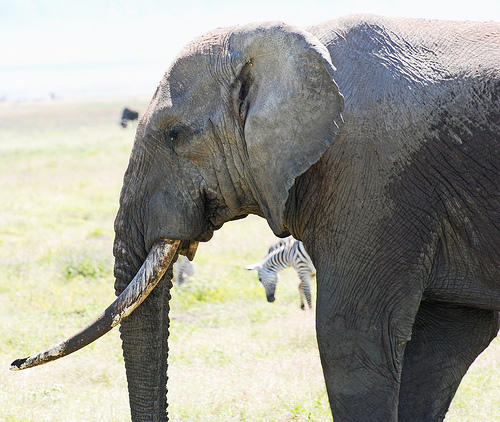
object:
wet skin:
[360, 75, 500, 291]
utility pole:
[243, 232, 316, 309]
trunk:
[113, 238, 199, 422]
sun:
[353, 0, 500, 90]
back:
[308, 13, 499, 154]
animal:
[8, 15, 499, 422]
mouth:
[141, 189, 224, 264]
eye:
[156, 123, 192, 149]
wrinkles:
[298, 60, 500, 312]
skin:
[105, 12, 500, 422]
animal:
[240, 235, 326, 311]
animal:
[120, 105, 140, 130]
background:
[0, 0, 497, 163]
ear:
[242, 18, 346, 239]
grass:
[0, 96, 500, 422]